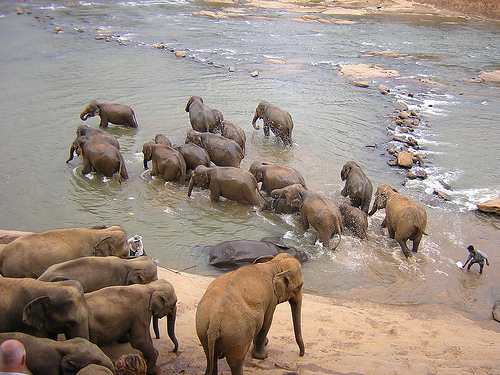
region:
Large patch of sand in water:
[334, 59, 401, 79]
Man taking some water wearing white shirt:
[457, 240, 488, 274]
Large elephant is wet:
[205, 230, 311, 271]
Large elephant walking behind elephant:
[365, 181, 431, 260]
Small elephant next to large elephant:
[334, 201, 370, 241]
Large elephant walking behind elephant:
[178, 160, 270, 207]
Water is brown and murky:
[0, 0, 499, 336]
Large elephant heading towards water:
[192, 253, 314, 374]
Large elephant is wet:
[249, 156, 311, 195]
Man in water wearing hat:
[120, 232, 147, 257]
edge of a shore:
[363, 294, 378, 322]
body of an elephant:
[231, 284, 247, 300]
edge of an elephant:
[253, 243, 263, 260]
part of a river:
[371, 260, 389, 285]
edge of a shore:
[306, 300, 325, 332]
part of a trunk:
[293, 298, 305, 325]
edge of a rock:
[403, 153, 413, 172]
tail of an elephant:
[281, 163, 299, 201]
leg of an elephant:
[232, 348, 247, 355]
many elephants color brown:
[5, 68, 495, 373]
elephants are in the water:
[65, 82, 442, 265]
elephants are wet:
[55, 88, 375, 269]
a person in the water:
[452, 244, 489, 281]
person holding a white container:
[452, 242, 492, 277]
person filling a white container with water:
[448, 240, 495, 284]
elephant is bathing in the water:
[201, 231, 316, 268]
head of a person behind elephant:
[0, 334, 42, 374]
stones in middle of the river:
[380, 34, 495, 184]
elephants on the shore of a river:
[7, 231, 328, 373]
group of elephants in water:
[68, 83, 430, 258]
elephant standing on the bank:
[188, 251, 307, 373]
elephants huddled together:
[0, 218, 156, 371]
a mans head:
[3, 338, 31, 373]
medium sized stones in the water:
[386, 79, 447, 207]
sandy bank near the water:
[179, 268, 482, 374]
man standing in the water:
[466, 238, 491, 278]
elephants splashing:
[270, 171, 429, 267]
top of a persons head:
[108, 351, 148, 373]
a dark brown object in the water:
[213, 230, 317, 268]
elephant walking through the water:
[245, 96, 302, 147]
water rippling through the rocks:
[372, 88, 436, 185]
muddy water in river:
[320, 249, 442, 301]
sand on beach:
[315, 319, 447, 374]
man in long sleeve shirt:
[458, 231, 493, 284]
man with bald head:
[2, 337, 32, 374]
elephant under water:
[185, 235, 316, 278]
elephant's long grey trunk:
[290, 297, 309, 362]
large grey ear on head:
[195, 169, 211, 186]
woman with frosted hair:
[110, 352, 150, 372]